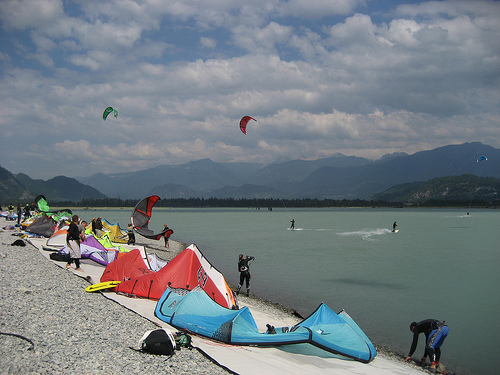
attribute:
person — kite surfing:
[283, 209, 300, 238]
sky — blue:
[230, 13, 314, 70]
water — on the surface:
[292, 235, 487, 313]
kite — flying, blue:
[139, 278, 390, 364]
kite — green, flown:
[87, 100, 123, 126]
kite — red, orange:
[229, 110, 270, 140]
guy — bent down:
[403, 307, 453, 361]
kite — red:
[235, 114, 260, 137]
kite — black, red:
[128, 185, 179, 242]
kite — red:
[104, 242, 198, 289]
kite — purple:
[84, 233, 114, 267]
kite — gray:
[133, 210, 149, 247]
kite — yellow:
[98, 218, 126, 247]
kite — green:
[35, 194, 70, 221]